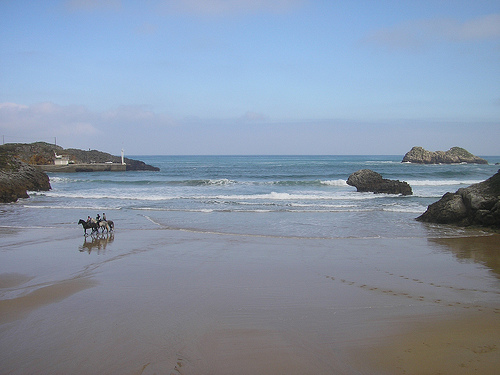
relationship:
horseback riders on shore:
[79, 215, 114, 234] [1, 205, 498, 375]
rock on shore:
[419, 171, 499, 230] [1, 205, 499, 243]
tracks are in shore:
[324, 266, 499, 314] [1, 205, 498, 375]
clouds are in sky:
[1, 104, 499, 155] [0, 0, 499, 155]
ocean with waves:
[41, 157, 498, 197] [21, 176, 483, 212]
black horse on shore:
[77, 218, 99, 236] [1, 205, 498, 375]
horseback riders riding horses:
[86, 215, 91, 227] [79, 213, 115, 236]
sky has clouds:
[0, 0, 499, 155] [1, 104, 499, 155]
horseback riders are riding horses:
[86, 215, 91, 227] [79, 213, 115, 236]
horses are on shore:
[79, 213, 115, 236] [1, 205, 498, 375]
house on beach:
[53, 155, 71, 165] [42, 163, 126, 170]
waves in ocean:
[21, 176, 483, 212] [41, 157, 498, 197]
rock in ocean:
[419, 171, 499, 230] [41, 157, 498, 197]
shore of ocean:
[1, 205, 499, 243] [41, 157, 498, 197]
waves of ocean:
[21, 176, 483, 212] [41, 157, 498, 197]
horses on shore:
[79, 213, 115, 236] [1, 205, 499, 243]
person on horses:
[101, 213, 107, 223] [100, 218, 116, 233]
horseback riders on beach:
[86, 215, 91, 227] [127, 208, 423, 343]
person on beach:
[95, 214, 101, 223] [127, 208, 423, 343]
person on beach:
[101, 213, 107, 223] [127, 208, 423, 343]